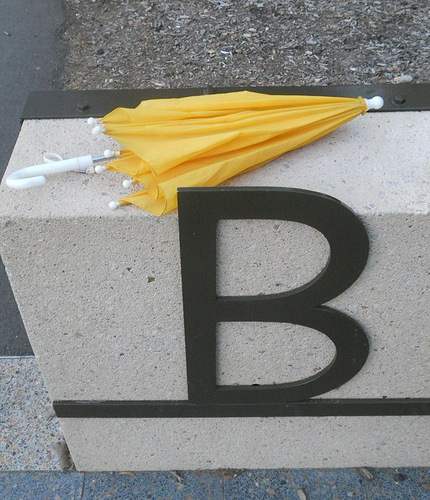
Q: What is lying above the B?
A: Umbrella.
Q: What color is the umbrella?
A: Yellow.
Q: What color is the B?
A: Black.